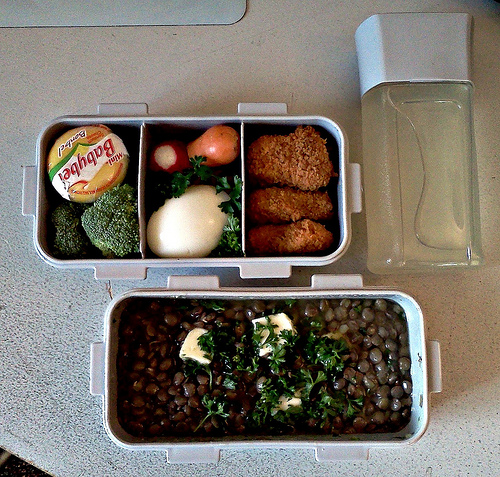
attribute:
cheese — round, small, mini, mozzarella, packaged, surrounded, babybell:
[55, 73, 126, 184]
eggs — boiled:
[148, 187, 230, 265]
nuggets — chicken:
[248, 81, 324, 252]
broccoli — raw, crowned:
[74, 198, 162, 265]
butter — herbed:
[181, 341, 351, 359]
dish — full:
[76, 297, 134, 426]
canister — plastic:
[333, 21, 495, 269]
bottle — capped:
[340, 69, 455, 190]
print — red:
[61, 139, 130, 180]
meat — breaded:
[250, 132, 311, 182]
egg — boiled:
[158, 178, 252, 232]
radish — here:
[145, 123, 200, 182]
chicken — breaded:
[242, 181, 308, 234]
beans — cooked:
[133, 316, 204, 441]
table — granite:
[101, 40, 272, 102]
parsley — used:
[217, 175, 247, 234]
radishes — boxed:
[145, 133, 228, 200]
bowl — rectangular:
[49, 92, 224, 282]